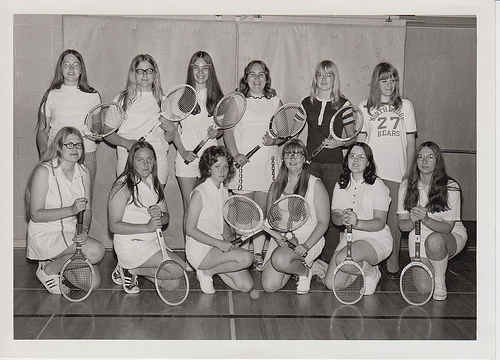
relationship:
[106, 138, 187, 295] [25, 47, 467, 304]
girl on tennis team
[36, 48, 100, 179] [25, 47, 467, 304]
girl on tennis team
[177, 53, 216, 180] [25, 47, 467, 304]
girl on tennis team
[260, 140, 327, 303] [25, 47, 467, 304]
girl on tennis team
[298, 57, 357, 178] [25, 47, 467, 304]
girl on tennis team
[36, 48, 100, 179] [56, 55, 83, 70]
girl wearing glasses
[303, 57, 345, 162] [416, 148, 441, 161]
girl wearing glasses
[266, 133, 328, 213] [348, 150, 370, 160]
girl wearing glasses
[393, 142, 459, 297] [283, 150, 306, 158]
girl wearing glasses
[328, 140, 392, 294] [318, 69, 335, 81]
girl wearing glasses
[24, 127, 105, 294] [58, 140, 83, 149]
girl wearing glasses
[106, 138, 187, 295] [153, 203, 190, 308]
girl holding tennis racket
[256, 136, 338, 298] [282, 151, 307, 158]
woman wearing glasses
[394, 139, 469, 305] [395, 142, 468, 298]
female is a tennis player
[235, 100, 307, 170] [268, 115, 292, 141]
tennis racket is black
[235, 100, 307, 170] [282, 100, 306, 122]
tennis racket is white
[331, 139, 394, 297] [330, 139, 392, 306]
female is a tennis player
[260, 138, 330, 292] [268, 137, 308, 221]
girl with pigtails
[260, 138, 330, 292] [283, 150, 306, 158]
girl with glasses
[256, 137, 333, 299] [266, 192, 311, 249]
member crossing racket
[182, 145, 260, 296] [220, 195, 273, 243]
member crossing racket